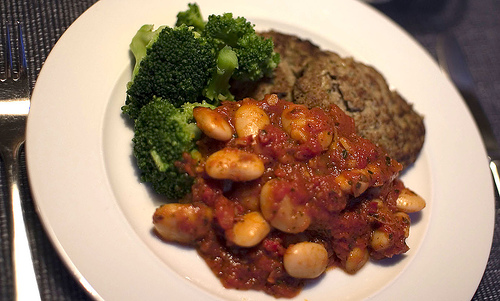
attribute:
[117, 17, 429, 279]
food — pile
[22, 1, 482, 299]
plate — white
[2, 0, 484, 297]
photo — high quality